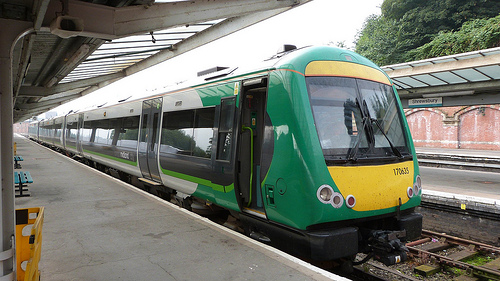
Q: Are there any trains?
A: Yes, there is a train.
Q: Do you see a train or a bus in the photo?
A: Yes, there is a train.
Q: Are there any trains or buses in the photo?
A: Yes, there is a train.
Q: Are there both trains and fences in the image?
A: No, there is a train but no fences.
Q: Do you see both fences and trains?
A: No, there is a train but no fences.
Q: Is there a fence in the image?
A: No, there are no fences.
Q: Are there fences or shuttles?
A: No, there are no fences or shuttles.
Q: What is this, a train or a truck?
A: This is a train.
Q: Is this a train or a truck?
A: This is a train.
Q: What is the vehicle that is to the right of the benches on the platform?
A: The vehicle is a train.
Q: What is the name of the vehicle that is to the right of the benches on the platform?
A: The vehicle is a train.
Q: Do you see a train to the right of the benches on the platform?
A: Yes, there is a train to the right of the benches.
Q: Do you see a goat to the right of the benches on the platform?
A: No, there is a train to the right of the benches.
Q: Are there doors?
A: Yes, there is a door.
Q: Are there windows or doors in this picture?
A: Yes, there is a door.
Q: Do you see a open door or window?
A: Yes, there is an open door.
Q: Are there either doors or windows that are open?
A: Yes, the door is open.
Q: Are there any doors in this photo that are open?
A: Yes, there is an open door.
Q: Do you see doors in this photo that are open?
A: Yes, there is a door that is open.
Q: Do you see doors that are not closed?
A: Yes, there is a open door.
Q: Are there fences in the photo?
A: No, there are no fences.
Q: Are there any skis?
A: No, there are no skis.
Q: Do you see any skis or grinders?
A: No, there are no skis or grinders.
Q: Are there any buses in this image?
A: No, there are no buses.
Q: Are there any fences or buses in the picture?
A: No, there are no buses or fences.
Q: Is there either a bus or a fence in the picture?
A: No, there are no buses or fences.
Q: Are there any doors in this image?
A: Yes, there are doors.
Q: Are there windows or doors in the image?
A: Yes, there are doors.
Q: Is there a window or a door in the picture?
A: Yes, there are doors.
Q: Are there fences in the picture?
A: No, there are no fences.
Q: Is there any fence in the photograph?
A: No, there are no fences.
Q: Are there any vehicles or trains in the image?
A: Yes, there is a train.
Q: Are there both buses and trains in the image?
A: No, there is a train but no buses.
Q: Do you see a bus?
A: No, there are no buses.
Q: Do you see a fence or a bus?
A: No, there are no buses or fences.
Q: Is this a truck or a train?
A: This is a train.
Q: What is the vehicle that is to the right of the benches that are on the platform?
A: The vehicle is a train.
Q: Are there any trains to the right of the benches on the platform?
A: Yes, there is a train to the right of the benches.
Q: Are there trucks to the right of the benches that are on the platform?
A: No, there is a train to the right of the benches.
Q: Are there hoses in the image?
A: No, there are no hoses.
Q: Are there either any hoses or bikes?
A: No, there are no hoses or bikes.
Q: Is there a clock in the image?
A: No, there are no clocks.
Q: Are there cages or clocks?
A: No, there are no clocks or cages.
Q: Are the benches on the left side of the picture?
A: Yes, the benches are on the left of the image.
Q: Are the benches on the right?
A: No, the benches are on the left of the image.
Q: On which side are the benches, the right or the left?
A: The benches are on the left of the image.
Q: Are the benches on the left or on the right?
A: The benches are on the left of the image.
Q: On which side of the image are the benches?
A: The benches are on the left of the image.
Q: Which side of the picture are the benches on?
A: The benches are on the left of the image.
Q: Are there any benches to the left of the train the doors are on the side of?
A: Yes, there are benches to the left of the train.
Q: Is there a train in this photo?
A: Yes, there is a train.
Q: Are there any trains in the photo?
A: Yes, there is a train.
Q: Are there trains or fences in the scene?
A: Yes, there is a train.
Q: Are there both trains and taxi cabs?
A: No, there is a train but no taxis.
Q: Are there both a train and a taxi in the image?
A: No, there is a train but no taxis.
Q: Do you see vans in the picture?
A: No, there are no vans.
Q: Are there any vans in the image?
A: No, there are no vans.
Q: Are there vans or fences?
A: No, there are no vans or fences.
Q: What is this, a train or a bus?
A: This is a train.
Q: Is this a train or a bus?
A: This is a train.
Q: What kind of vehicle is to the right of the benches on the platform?
A: The vehicle is a train.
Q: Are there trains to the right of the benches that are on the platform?
A: Yes, there is a train to the right of the benches.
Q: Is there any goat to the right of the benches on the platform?
A: No, there is a train to the right of the benches.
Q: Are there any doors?
A: Yes, there are doors.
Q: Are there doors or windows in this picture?
A: Yes, there are doors.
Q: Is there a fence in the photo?
A: No, there are no fences.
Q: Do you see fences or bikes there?
A: No, there are no fences or bikes.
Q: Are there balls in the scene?
A: No, there are no balls.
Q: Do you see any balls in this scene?
A: No, there are no balls.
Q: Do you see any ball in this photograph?
A: No, there are no balls.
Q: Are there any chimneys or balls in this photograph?
A: No, there are no balls or chimneys.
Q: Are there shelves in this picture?
A: No, there are no shelves.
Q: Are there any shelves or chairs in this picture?
A: No, there are no shelves or chairs.